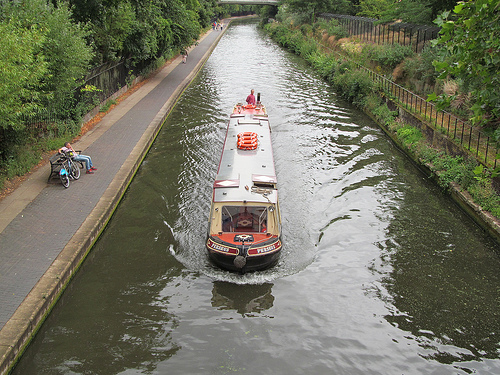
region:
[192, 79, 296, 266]
boat traveling on waterway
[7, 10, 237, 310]
sidewalk running along waterway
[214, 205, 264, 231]
front window of boat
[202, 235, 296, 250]
white lettering on red background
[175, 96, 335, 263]
wake created by boat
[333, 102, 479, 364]
ripples on the waterway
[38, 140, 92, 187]
bench on the sidewalk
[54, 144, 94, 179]
person sitting on bench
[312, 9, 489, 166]
black fenceline along waterway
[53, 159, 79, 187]
bicycle leaning on bench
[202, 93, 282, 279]
A longboat on a river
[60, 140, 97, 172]
A man on a bench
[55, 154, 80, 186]
A bicycle leaning on a bench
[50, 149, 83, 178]
A small park bench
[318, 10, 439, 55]
A section of railing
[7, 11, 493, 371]
A long narrow river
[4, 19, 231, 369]
A long pathway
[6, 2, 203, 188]
A large section of trees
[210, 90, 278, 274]
A long narrow white boat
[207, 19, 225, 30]
A small group of people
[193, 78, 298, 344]
a boat in the water canal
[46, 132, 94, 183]
a man seated down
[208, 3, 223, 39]
people walking along the canal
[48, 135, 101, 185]
the man has red shoes and blue jeans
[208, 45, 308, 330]
the water is calm with no rapids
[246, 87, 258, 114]
a man is standing on the boat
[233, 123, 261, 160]
red lifeboats on the boat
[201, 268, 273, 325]
reflection of the ship on the water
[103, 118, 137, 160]
the pavement has grey slabs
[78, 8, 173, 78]
the trees are hanging out on the road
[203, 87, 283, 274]
A boat in the middle of the water.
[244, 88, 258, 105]
A person standing on the back of a boat.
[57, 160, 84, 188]
A bicycle resting against a bench.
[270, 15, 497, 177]
A long metal fence.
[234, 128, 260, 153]
Orange and white life preservers on top of a boat.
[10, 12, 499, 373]
A long waterway.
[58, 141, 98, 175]
A man slumped on a bench.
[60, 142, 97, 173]
A person wearing blue jeans.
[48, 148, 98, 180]
A bench on the sidewalk.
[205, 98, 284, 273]
A long boat.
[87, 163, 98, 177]
Person wearing red shoes.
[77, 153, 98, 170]
Person wearing blue jeans.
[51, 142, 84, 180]
Person sitting on bench.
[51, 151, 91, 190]
Bike leaning against bench.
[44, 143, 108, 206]
Bike is blue in color.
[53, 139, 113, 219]
Bike is near person on bench.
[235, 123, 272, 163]
3 red rings on top of boat.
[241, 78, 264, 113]
Person standing on back of boat.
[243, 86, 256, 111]
Person wearing red shirt.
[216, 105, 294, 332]
Boat floating down river.